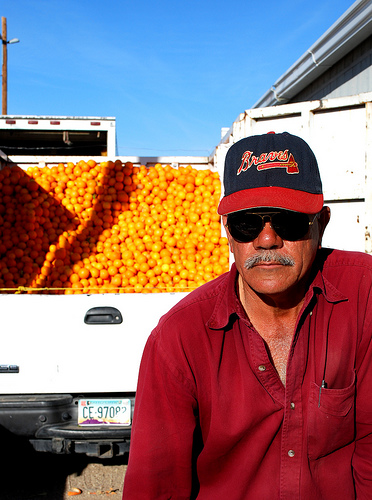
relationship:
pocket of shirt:
[302, 367, 356, 461] [122, 247, 370, 498]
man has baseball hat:
[118, 131, 371, 499] [216, 130, 322, 212]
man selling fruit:
[118, 131, 371, 499] [20, 122, 228, 302]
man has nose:
[201, 152, 351, 315] [253, 222, 281, 251]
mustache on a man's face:
[223, 234, 308, 277] [197, 127, 335, 344]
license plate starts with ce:
[76, 395, 131, 423] [82, 403, 96, 418]